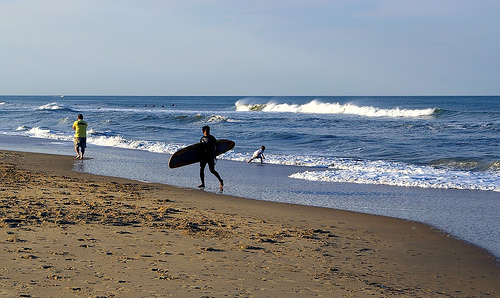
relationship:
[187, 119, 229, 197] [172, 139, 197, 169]
man carrying board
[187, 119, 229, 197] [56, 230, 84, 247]
man walking on sand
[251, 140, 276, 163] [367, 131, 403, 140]
child in water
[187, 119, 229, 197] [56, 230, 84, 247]
man on sand